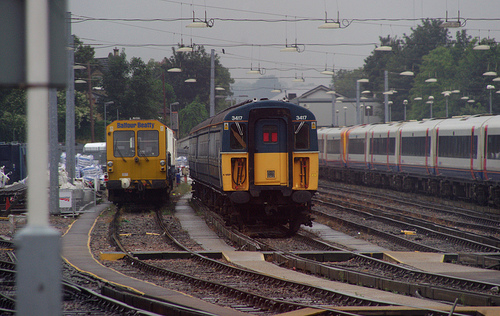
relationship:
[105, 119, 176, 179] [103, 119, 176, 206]
yellow train car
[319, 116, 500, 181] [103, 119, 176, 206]
white train car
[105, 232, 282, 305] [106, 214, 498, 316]
curved train track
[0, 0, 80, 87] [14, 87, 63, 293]
sign on a pole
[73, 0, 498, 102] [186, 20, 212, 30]
power line lights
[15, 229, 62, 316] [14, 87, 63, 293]
grey metal pole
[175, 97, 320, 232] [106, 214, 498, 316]
trains on tracks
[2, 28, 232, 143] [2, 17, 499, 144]
full green trees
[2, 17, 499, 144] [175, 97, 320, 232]
trees behind trains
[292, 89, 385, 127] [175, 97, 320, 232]
house behind trains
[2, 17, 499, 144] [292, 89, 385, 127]
trees beside house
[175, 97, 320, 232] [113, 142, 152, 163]
trains with wipers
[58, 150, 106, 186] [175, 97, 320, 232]
bags by trains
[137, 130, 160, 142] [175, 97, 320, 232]
windows of a trains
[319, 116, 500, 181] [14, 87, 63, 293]
white electric pole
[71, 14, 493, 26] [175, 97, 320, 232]
wires above trains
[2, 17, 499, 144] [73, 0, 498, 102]
trees in horizon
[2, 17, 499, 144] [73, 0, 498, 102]
trees near horizon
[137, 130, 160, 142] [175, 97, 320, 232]
windows of trains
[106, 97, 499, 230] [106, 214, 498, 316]
trains on tracks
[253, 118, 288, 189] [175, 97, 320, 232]
door on trains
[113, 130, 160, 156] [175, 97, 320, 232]
windows on a trains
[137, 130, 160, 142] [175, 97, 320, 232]
windows on a trains